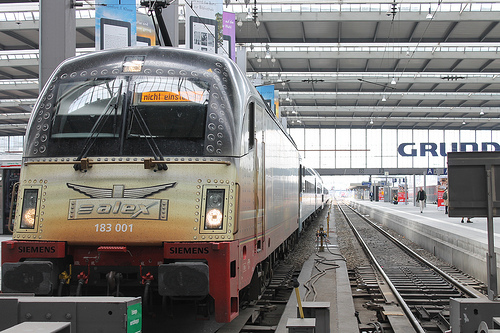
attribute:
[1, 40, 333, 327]
train — pictured, orange , long 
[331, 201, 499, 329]
train tracks — metal 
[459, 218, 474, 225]
shoes — black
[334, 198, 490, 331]
rail line — pictured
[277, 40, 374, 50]
lightings — pictured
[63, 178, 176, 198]
eagle logo — pictured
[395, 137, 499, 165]
grudd — black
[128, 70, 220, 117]
sign — yellow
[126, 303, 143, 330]
stick — green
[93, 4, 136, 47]
sign — blue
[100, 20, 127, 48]
phone — smart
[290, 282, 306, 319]
pole — yellow, black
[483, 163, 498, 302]
pole — black, yellow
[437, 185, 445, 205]
black bag — black 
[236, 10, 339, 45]
ceiling — metal, glass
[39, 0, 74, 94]
beam — square 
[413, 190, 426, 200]
jacket — black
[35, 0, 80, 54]
pillar — metal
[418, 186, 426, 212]
man — pictured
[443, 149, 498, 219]
sign — metal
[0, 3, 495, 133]
roof — metal 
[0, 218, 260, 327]
train bottom — red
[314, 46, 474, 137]
lights — bright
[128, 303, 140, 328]
letters — white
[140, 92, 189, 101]
letters — black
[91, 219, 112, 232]
number — white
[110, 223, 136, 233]
number — white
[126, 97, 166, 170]
windshield wiper — black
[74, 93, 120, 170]
windshield wiper — black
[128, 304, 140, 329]
lettering — white